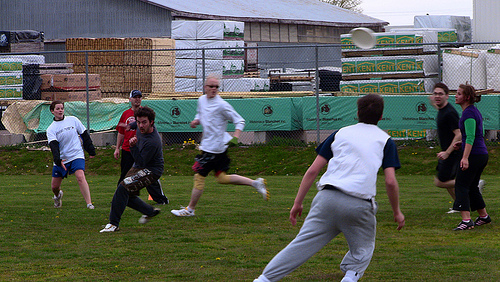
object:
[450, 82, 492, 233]
girl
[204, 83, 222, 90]
sunglasses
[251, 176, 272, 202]
shoe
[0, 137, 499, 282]
grass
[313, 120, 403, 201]
shirt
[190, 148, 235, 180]
black shorts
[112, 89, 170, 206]
man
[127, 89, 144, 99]
hat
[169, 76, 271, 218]
man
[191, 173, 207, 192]
brace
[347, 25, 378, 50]
frisbee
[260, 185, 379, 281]
sweat pants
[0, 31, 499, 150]
fence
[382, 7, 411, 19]
air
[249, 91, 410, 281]
man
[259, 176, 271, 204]
bottom